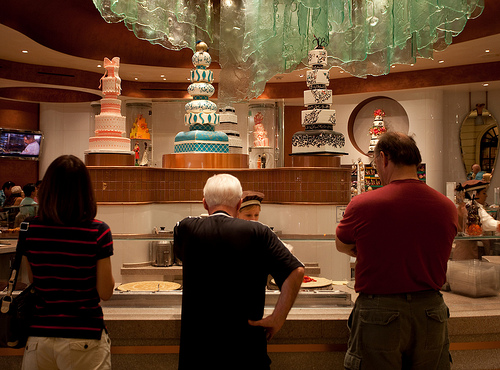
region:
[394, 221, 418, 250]
man wearing a burgandy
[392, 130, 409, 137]
man has a ball spot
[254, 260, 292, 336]
man hand on his hip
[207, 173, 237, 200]
man has grey hair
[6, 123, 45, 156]
television hanging from the ceiling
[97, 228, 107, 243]
red strips in the shirt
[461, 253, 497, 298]
white plates stacked on side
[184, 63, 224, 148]
cake on the top shelf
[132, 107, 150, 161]
dolls on the shelf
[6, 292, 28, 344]
woman carrying a black purse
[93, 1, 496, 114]
glass decor hanging from the ceiling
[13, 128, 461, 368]
people standing next to each other looking at items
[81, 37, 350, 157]
beautiful and tall cakes arranged around the room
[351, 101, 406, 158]
a cake sits in the wall as decor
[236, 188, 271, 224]
the woman keeps her hair back with a hat and net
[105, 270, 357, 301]
desserts that customers can buy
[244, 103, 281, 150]
a tall cake in a glass case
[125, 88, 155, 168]
a smaller cake set in a glass case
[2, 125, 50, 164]
a television on the wall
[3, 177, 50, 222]
a group of people sitting down and enjoying themselves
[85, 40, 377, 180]
three cakes on display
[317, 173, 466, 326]
the shirt is red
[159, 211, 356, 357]
the shirt is black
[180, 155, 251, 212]
the hair is gray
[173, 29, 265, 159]
the cake is blue and white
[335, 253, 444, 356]
the pants are brown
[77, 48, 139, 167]
Large orange and white multi-tiered cake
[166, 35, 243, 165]
Blue and white multi-layered cake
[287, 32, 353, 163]
White multi-layered cake with black designs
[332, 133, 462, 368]
Man in red shirt with arms folded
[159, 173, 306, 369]
Man in a black shirt with hand on hip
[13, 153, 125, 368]
Woman in a red and black striped shirt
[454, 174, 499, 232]
Woman working in a cake bakery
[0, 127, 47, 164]
Flat screened t.v. hanging from a wall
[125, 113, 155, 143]
Square orange multi-layered cake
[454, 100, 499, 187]
Oblong shaped mirror on a wall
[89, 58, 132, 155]
White Cake With Pink Trim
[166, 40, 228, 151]
White Iced Cake With Blue Trim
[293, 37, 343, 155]
White Iced Cake With Purple Iced Decorations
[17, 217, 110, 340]
Woman's Blue and Red Stripped Shirt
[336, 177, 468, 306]
Male Maroon Short Sleeved Shirt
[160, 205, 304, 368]
Male Black Tee Shirt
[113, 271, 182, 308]
Clean Empty Cake Platter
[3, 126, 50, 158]
Television on the wall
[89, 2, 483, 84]
Green Hanging Glass From Ceiling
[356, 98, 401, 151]
White Iced Cake With Red Flowers